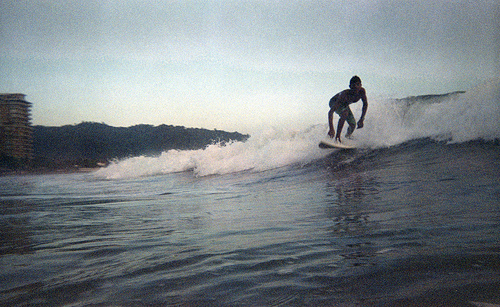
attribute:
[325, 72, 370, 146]
surfer — surfing, man, young, male, human, woman, crouched over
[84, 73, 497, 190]
wave — breaking, ocean wave, large, white, foamy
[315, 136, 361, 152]
surfboard — white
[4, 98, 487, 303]
water — dark, rippled, large area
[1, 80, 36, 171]
building — multi-story, large, distant, tall, multi level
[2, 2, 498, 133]
sky — overcast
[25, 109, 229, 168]
mountain — distant, large, small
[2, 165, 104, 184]
beach — strip, sandy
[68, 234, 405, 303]
ripples — small